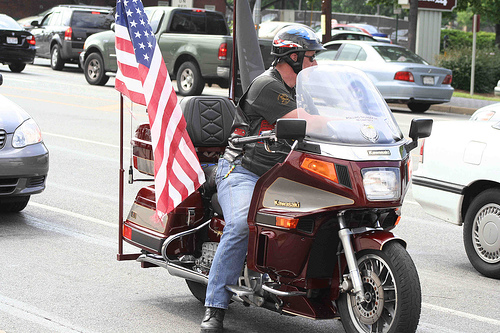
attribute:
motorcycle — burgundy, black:
[112, 62, 436, 332]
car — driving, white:
[405, 106, 499, 281]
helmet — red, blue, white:
[266, 23, 327, 76]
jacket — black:
[227, 66, 301, 176]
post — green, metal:
[319, 0, 334, 47]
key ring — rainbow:
[213, 153, 236, 181]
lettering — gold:
[271, 197, 302, 211]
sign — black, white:
[166, 0, 195, 12]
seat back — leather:
[172, 93, 244, 150]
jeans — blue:
[203, 154, 265, 313]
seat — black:
[198, 161, 242, 214]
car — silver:
[308, 37, 455, 116]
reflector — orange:
[117, 223, 139, 243]